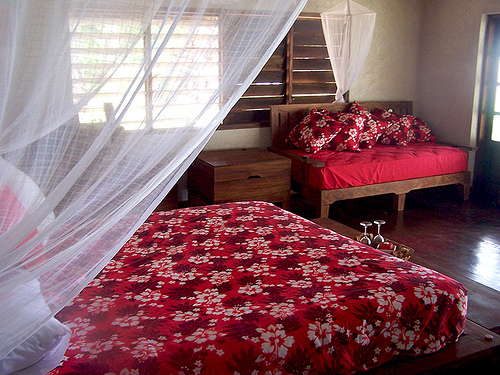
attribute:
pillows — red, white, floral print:
[296, 103, 432, 146]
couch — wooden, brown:
[301, 153, 470, 187]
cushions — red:
[320, 114, 421, 140]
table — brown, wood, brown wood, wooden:
[200, 146, 287, 192]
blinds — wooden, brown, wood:
[269, 37, 321, 97]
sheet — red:
[336, 159, 375, 172]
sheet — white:
[262, 200, 270, 208]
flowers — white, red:
[227, 210, 261, 222]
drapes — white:
[107, 15, 226, 89]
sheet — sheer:
[186, 16, 237, 55]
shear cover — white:
[318, 9, 378, 80]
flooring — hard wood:
[420, 199, 461, 219]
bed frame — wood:
[424, 352, 466, 373]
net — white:
[29, 120, 83, 177]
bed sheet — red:
[329, 157, 373, 176]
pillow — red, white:
[362, 115, 385, 148]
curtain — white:
[192, 22, 226, 67]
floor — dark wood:
[422, 226, 450, 254]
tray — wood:
[330, 225, 350, 234]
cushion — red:
[401, 115, 437, 143]